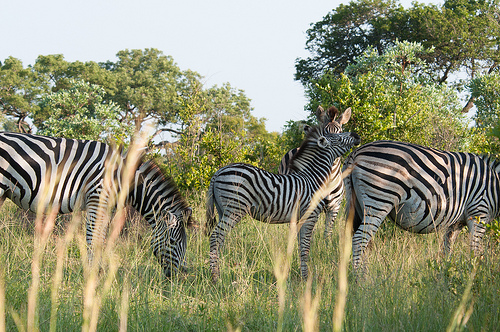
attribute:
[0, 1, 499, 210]
leaves — green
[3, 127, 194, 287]
zebra — large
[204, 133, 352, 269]
zebra — baby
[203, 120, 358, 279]
zebra — baby, striped, black, white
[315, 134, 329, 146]
ear — small